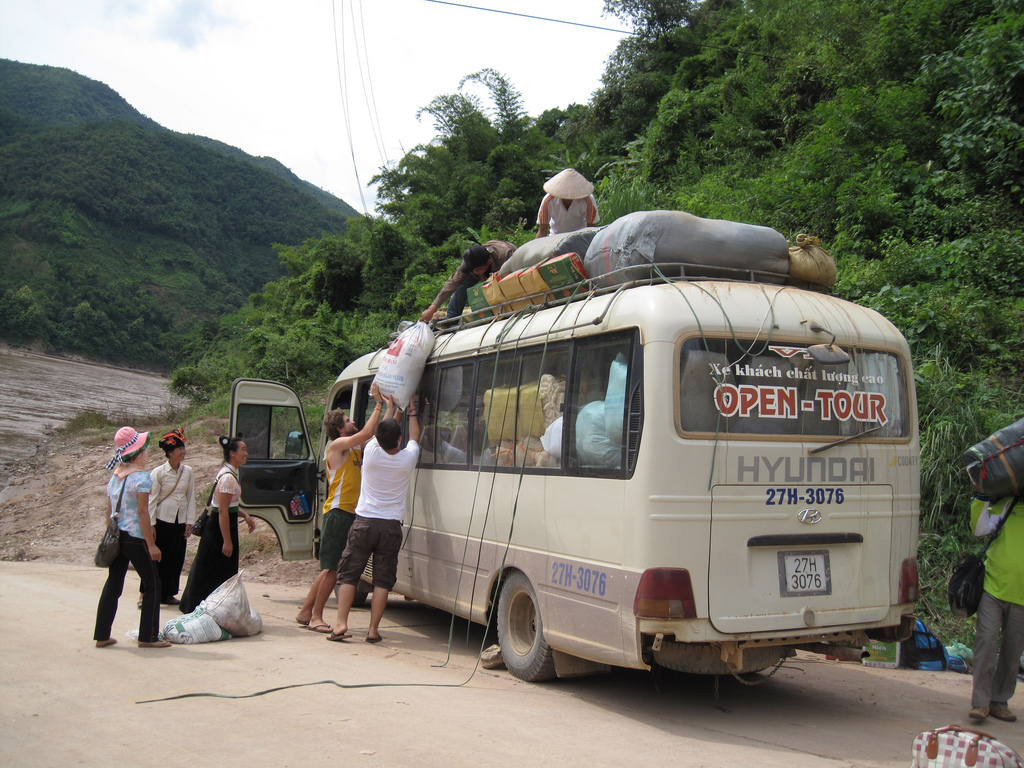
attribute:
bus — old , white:
[217, 284, 935, 686]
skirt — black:
[179, 501, 240, 653]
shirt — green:
[966, 498, 1021, 600]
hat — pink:
[104, 415, 154, 465]